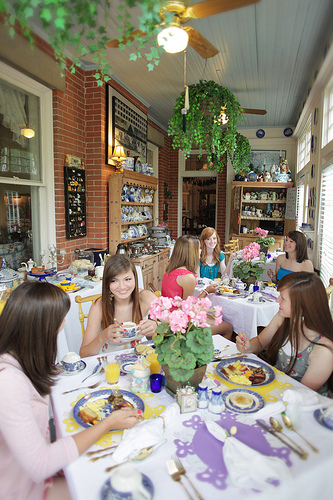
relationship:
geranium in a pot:
[166, 79, 248, 167] [200, 97, 225, 122]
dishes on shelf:
[121, 184, 155, 202] [120, 200, 154, 208]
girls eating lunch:
[75, 235, 135, 368] [103, 317, 165, 376]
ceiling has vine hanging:
[2, 1, 332, 129] [166, 79, 248, 167]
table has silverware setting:
[49, 334, 330, 499] [167, 411, 319, 499]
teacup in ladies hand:
[117, 322, 141, 338] [137, 316, 159, 338]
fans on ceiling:
[106, 0, 267, 122] [2, 1, 332, 129]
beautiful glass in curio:
[121, 184, 155, 202] [107, 168, 171, 294]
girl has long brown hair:
[235, 252, 332, 393] [267, 271, 332, 390]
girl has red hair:
[197, 226, 228, 281] [200, 226, 221, 268]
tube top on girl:
[274, 265, 295, 284] [267, 230, 314, 281]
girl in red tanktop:
[159, 234, 234, 341] [162, 268, 198, 302]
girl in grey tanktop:
[235, 252, 332, 393] [270, 315, 325, 383]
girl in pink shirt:
[0, 278, 144, 500] [0, 351, 81, 498]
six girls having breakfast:
[0, 226, 331, 499] [51, 268, 331, 498]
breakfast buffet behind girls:
[230, 179, 298, 252] [0, 226, 331, 499]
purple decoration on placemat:
[174, 410, 292, 489] [164, 405, 300, 499]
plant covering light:
[166, 79, 248, 167] [214, 106, 231, 128]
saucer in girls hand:
[115, 335, 140, 345] [103, 322, 128, 343]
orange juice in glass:
[104, 366, 121, 384] [101, 358, 122, 385]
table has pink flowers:
[49, 334, 330, 499] [147, 294, 223, 332]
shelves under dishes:
[120, 200, 153, 245] [121, 186, 155, 242]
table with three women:
[49, 334, 330, 499] [0, 226, 331, 499]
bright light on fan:
[157, 27, 188, 54] [106, 1, 260, 58]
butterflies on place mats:
[174, 410, 292, 489] [165, 402, 305, 496]